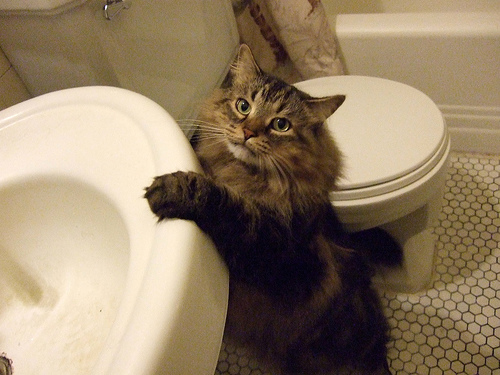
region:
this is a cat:
[142, 58, 407, 371]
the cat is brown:
[154, 65, 396, 372]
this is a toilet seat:
[272, 58, 457, 313]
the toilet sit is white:
[249, 73, 461, 313]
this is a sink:
[0, 78, 229, 373]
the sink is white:
[0, 85, 233, 373]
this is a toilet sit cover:
[297, 77, 441, 199]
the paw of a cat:
[144, 159, 224, 224]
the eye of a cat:
[266, 108, 298, 145]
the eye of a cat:
[228, 96, 253, 117]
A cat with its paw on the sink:
[140, 40, 373, 269]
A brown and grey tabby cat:
[140, 37, 406, 370]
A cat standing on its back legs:
[144, 39, 413, 372]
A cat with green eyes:
[230, 91, 296, 136]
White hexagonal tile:
[380, 143, 497, 373]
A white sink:
[5, 83, 235, 372]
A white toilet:
[5, 1, 461, 294]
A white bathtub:
[325, 0, 498, 153]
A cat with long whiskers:
[168, 100, 306, 195]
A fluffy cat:
[138, 35, 408, 367]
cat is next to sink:
[186, 70, 388, 336]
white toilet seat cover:
[264, 60, 458, 230]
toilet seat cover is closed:
[232, 53, 456, 213]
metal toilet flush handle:
[96, 0, 136, 37]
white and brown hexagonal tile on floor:
[434, 160, 492, 373]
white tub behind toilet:
[302, 2, 490, 133]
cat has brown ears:
[219, 49, 341, 119]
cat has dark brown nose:
[233, 126, 260, 152]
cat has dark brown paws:
[129, 167, 211, 239]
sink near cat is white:
[2, 77, 188, 362]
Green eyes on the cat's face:
[230, 94, 305, 144]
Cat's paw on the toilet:
[143, 160, 216, 238]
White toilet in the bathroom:
[8, 110, 233, 374]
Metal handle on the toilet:
[100, 0, 142, 35]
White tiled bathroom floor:
[435, 308, 497, 356]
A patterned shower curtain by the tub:
[237, 0, 350, 104]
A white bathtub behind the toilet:
[340, 22, 498, 103]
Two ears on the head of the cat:
[222, 38, 352, 123]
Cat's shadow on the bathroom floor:
[393, 286, 466, 363]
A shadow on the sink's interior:
[10, 258, 61, 330]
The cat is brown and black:
[146, 42, 398, 371]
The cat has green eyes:
[233, 88, 296, 138]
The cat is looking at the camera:
[212, 44, 343, 177]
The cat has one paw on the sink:
[149, 37, 404, 369]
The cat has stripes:
[150, 34, 400, 366]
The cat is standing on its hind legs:
[156, 41, 405, 373]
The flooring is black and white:
[371, 152, 496, 369]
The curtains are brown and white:
[238, 13, 346, 87]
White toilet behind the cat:
[18, 12, 443, 295]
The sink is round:
[3, 101, 227, 373]